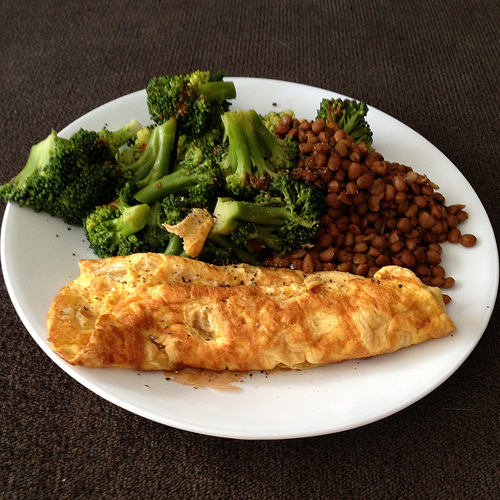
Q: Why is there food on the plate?
A: Someone is hungry.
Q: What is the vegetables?
A: Broccoli.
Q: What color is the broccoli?
A: Green.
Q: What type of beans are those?
A: Pinto.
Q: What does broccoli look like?
A: Small trees.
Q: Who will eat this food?
A: People.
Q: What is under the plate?
A: Fabric.